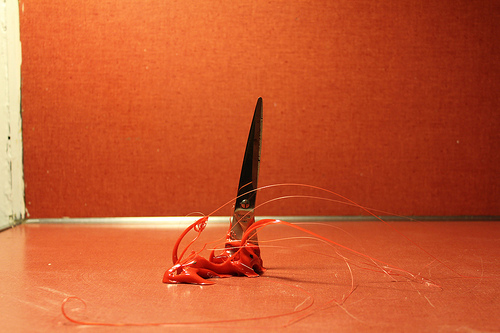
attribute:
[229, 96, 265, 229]
scissors — metal, silver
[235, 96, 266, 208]
blades — silver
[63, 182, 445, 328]
handle — melted, orange, plastic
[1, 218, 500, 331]
floor — orange, red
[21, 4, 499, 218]
door — wooden, red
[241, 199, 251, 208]
rivet — silver, metal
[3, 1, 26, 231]
frame — wooden, white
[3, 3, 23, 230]
paint — peeling, white